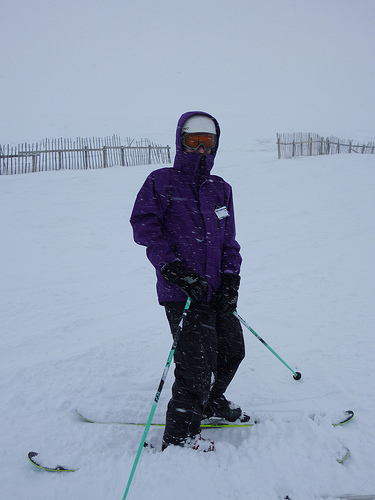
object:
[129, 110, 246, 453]
person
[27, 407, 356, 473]
skis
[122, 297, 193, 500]
pole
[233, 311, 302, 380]
pole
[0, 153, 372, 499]
snow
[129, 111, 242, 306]
jacket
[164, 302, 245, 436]
pants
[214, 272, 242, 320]
glove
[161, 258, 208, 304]
glove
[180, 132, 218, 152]
goggles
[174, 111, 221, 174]
hood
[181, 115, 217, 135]
white helmet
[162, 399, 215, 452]
boot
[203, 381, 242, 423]
boot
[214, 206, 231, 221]
tag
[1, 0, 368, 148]
sky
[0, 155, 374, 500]
ground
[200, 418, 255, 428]
green ski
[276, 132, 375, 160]
fence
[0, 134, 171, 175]
fence